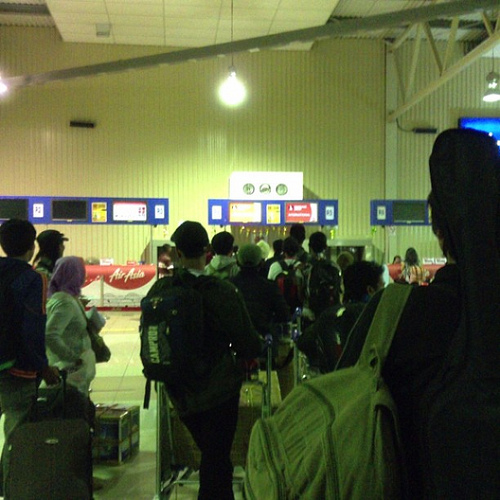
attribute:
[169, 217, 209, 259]
hat — black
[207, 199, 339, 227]
panels — blue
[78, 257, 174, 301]
counter — Air Asia airline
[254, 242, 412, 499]
backpack — wide, droopy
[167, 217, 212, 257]
cap — black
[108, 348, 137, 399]
tiles — yellow, tan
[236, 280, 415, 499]
backpack — light colored, tan, hanging, light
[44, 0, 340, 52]
ceiling — white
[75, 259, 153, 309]
counter — red, white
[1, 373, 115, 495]
suitcase — wheeled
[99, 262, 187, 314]
sign — Air Asia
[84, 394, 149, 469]
box — tied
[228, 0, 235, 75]
wire — single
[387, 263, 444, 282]
counter — red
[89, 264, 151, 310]
sign — red, white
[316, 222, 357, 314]
people — large group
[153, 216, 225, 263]
cap — black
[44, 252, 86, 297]
headscarf — purple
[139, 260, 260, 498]
clothes — dark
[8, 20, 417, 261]
lines — yellow, gray, vertical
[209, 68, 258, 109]
light — round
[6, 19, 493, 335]
wall — tall, yellow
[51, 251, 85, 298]
scarf — purple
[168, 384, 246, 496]
legs — crossed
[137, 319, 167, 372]
writing — white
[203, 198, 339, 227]
sign — multicolored, informational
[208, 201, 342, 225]
background — bright blue